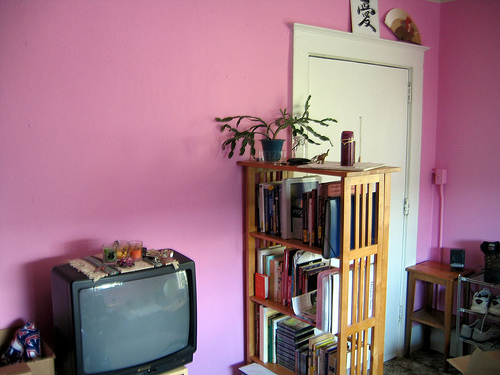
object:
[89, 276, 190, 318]
glare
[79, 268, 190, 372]
screen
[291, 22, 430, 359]
door frame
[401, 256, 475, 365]
table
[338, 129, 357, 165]
bottle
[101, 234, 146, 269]
candles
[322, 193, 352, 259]
blue folder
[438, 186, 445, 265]
pipe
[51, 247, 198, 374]
set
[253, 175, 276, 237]
books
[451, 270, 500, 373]
shoe rack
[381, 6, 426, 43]
fan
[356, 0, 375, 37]
chinese character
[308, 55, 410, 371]
door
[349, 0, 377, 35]
sign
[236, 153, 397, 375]
book case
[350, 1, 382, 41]
paper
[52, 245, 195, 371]
black tv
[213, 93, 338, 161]
plant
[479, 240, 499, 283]
shoe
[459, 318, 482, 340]
shoe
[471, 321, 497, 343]
shoe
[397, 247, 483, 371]
night stand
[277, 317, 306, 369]
dvds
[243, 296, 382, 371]
bottom shelf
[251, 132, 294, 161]
person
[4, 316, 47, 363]
piece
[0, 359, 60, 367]
box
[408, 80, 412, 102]
hinge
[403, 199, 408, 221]
hinge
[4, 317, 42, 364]
stuff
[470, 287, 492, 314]
shoe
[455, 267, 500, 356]
rack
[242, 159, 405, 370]
building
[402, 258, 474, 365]
stand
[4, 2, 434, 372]
wall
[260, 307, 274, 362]
books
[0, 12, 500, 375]
room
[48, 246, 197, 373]
television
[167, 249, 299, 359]
box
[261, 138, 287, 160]
pot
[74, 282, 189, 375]
reflection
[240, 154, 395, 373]
bookcase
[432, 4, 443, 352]
corner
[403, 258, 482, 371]
end table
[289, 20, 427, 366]
frame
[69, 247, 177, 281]
cloth